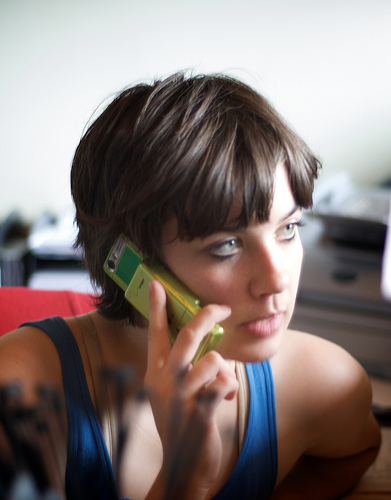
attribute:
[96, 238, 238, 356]
cell phone — green